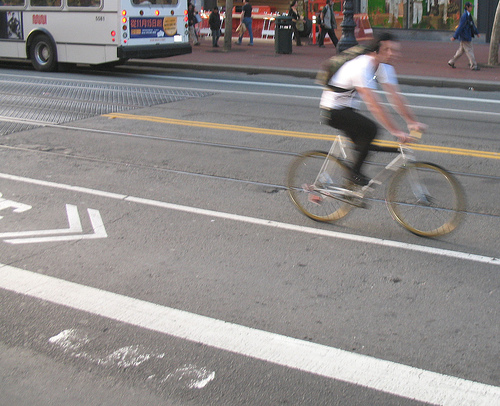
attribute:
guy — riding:
[315, 28, 430, 190]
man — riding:
[315, 31, 427, 193]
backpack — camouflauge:
[310, 36, 381, 97]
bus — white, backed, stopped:
[1, 0, 200, 75]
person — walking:
[445, 2, 488, 72]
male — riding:
[312, 30, 431, 193]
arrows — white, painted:
[0, 199, 112, 250]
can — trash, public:
[270, 15, 300, 58]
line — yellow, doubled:
[94, 106, 500, 162]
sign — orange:
[352, 13, 376, 40]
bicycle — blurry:
[283, 119, 472, 240]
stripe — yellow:
[99, 106, 499, 179]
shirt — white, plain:
[317, 50, 401, 119]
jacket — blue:
[450, 12, 482, 46]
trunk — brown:
[487, 0, 499, 72]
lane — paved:
[0, 171, 499, 403]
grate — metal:
[0, 71, 223, 139]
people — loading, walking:
[188, 0, 263, 51]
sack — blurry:
[317, 40, 379, 99]